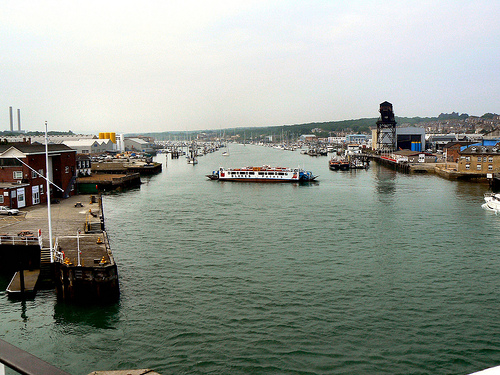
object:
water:
[199, 233, 423, 358]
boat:
[203, 161, 322, 188]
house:
[0, 142, 46, 213]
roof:
[61, 139, 113, 148]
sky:
[148, 31, 346, 103]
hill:
[314, 109, 481, 132]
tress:
[436, 112, 448, 130]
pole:
[38, 119, 59, 267]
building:
[0, 128, 102, 216]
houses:
[85, 127, 127, 151]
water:
[14, 133, 484, 368]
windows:
[228, 169, 235, 177]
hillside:
[264, 117, 434, 132]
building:
[70, 153, 93, 181]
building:
[374, 99, 399, 156]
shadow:
[373, 158, 398, 198]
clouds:
[68, 22, 180, 55]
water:
[142, 191, 473, 343]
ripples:
[216, 257, 390, 345]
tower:
[372, 101, 400, 159]